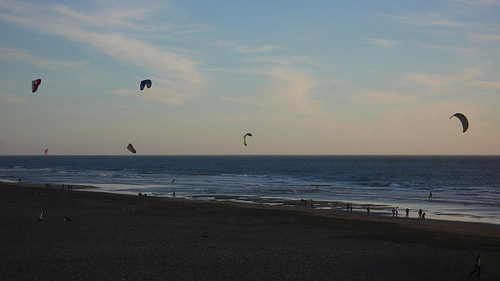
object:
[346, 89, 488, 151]
clouds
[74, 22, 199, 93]
clouds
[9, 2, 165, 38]
clouds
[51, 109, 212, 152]
clouds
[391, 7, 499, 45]
clouds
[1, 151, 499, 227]
ocean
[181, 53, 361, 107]
clouds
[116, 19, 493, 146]
sky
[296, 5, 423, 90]
sky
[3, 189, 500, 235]
ground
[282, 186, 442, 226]
people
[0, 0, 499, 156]
air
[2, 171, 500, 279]
beach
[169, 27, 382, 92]
sky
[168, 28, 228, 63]
blue plate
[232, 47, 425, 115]
blue plate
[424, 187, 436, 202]
person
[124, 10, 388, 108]
sky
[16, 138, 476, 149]
horizon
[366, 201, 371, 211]
person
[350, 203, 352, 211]
person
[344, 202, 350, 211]
person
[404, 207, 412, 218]
person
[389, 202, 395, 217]
person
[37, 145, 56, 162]
kite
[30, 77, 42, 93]
kite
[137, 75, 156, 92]
kite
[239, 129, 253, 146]
kite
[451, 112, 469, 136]
kite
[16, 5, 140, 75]
sky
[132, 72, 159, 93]
kite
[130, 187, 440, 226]
people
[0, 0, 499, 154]
clouds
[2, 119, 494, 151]
sky